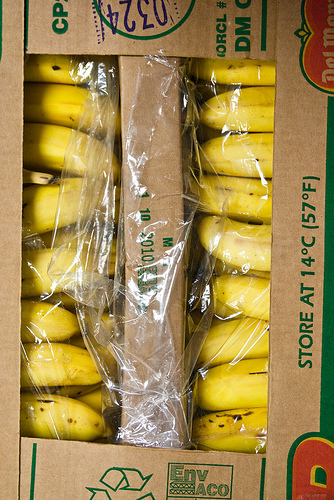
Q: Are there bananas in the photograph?
A: Yes, there are bananas.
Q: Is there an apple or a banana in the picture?
A: Yes, there are bananas.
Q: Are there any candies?
A: No, there are no candies.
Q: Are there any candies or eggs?
A: No, there are no candies or eggs.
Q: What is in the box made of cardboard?
A: The bananas are in the box.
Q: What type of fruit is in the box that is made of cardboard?
A: The fruits are bananas.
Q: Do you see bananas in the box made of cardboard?
A: Yes, there are bananas in the box.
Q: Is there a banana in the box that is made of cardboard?
A: Yes, there are bananas in the box.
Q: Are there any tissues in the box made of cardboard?
A: No, there are bananas in the box.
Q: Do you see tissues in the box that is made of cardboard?
A: No, there are bananas in the box.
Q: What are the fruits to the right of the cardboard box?
A: The fruits are bananas.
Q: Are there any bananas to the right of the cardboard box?
A: Yes, there are bananas to the right of the box.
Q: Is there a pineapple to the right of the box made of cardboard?
A: No, there are bananas to the right of the box.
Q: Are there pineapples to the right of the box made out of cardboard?
A: No, there are bananas to the right of the box.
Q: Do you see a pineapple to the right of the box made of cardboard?
A: No, there are bananas to the right of the box.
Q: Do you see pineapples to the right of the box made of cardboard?
A: No, there are bananas to the right of the box.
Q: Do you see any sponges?
A: No, there are no sponges.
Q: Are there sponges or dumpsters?
A: No, there are no sponges or dumpsters.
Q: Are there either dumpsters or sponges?
A: No, there are no sponges or dumpsters.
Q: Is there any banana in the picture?
A: Yes, there are bananas.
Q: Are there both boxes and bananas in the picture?
A: Yes, there are both bananas and a box.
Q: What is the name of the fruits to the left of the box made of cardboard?
A: The fruits are bananas.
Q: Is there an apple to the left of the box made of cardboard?
A: No, there are bananas to the left of the box.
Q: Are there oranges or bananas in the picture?
A: Yes, there are bananas.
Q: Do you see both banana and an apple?
A: No, there are bananas but no apples.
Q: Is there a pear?
A: No, there are no pears.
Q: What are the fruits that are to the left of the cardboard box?
A: The fruits are bananas.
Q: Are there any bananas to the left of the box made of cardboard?
A: Yes, there are bananas to the left of the box.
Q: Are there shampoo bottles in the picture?
A: No, there are no shampoo bottles.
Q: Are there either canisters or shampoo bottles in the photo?
A: No, there are no shampoo bottles or canisters.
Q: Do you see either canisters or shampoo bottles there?
A: No, there are no shampoo bottles or canisters.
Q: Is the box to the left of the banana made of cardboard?
A: Yes, the box is made of cardboard.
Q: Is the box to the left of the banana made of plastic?
A: No, the box is made of cardboard.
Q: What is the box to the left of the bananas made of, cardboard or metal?
A: The box is made of cardboard.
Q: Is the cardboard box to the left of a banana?
A: Yes, the box is to the left of a banana.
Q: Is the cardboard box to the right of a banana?
A: No, the box is to the left of a banana.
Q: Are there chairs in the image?
A: No, there are no chairs.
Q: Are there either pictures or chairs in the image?
A: No, there are no chairs or pictures.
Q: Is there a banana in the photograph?
A: Yes, there are bananas.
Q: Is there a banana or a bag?
A: Yes, there are bananas.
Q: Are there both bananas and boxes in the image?
A: Yes, there are both bananas and a box.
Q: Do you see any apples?
A: No, there are no apples.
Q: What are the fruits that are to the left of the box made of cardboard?
A: The fruits are bananas.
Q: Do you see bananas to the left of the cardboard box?
A: Yes, there are bananas to the left of the box.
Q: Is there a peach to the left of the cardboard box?
A: No, there are bananas to the left of the box.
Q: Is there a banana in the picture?
A: Yes, there is a banana.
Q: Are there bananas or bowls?
A: Yes, there is a banana.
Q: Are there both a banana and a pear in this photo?
A: No, there is a banana but no pears.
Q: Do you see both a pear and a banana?
A: No, there is a banana but no pears.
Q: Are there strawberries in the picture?
A: No, there are no strawberries.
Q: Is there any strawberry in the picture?
A: No, there are no strawberries.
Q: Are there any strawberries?
A: No, there are no strawberries.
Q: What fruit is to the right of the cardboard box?
A: The fruit is a banana.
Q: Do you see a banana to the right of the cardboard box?
A: Yes, there is a banana to the right of the box.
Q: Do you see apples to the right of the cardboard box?
A: No, there is a banana to the right of the box.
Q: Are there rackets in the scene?
A: No, there are no rackets.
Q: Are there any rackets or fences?
A: No, there are no rackets or fences.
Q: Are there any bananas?
A: Yes, there is a banana.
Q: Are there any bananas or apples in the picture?
A: Yes, there is a banana.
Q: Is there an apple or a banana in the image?
A: Yes, there is a banana.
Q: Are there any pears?
A: No, there are no pears.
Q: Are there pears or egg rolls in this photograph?
A: No, there are no pears or egg rolls.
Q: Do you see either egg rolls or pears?
A: No, there are no pears or egg rolls.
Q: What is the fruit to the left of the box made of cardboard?
A: The fruit is a banana.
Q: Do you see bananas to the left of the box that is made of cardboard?
A: Yes, there is a banana to the left of the box.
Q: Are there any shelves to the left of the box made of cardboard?
A: No, there is a banana to the left of the box.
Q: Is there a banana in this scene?
A: Yes, there is a banana.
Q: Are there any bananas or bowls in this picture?
A: Yes, there is a banana.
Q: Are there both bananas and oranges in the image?
A: No, there is a banana but no oranges.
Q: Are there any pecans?
A: No, there are no pecans.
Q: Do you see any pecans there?
A: No, there are no pecans.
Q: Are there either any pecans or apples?
A: No, there are no pecans or apples.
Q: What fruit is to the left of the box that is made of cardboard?
A: The fruit is a banana.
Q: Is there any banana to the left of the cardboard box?
A: Yes, there is a banana to the left of the box.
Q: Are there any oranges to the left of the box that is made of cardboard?
A: No, there is a banana to the left of the box.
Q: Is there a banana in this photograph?
A: Yes, there is a banana.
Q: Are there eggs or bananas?
A: Yes, there is a banana.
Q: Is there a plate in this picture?
A: No, there are no plates.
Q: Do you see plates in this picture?
A: No, there are no plates.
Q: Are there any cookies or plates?
A: No, there are no plates or cookies.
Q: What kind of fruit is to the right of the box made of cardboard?
A: The fruit is a banana.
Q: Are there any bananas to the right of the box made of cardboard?
A: Yes, there is a banana to the right of the box.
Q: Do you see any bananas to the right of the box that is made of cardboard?
A: Yes, there is a banana to the right of the box.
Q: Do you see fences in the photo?
A: No, there are no fences.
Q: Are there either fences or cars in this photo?
A: No, there are no fences or cars.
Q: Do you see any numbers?
A: Yes, there are numbers.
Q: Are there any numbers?
A: Yes, there are numbers.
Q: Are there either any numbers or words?
A: Yes, there are numbers.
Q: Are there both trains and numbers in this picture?
A: No, there are numbers but no trains.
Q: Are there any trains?
A: No, there are no trains.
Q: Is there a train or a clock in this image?
A: No, there are no trains or clocks.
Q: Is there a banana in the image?
A: Yes, there is a banana.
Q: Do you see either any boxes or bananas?
A: Yes, there is a banana.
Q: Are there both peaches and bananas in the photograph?
A: No, there is a banana but no peaches.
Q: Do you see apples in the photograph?
A: No, there are no apples.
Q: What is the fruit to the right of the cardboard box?
A: The fruit is a banana.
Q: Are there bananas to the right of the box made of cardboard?
A: Yes, there is a banana to the right of the box.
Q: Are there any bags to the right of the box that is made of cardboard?
A: No, there is a banana to the right of the box.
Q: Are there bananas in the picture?
A: Yes, there is a banana.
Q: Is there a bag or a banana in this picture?
A: Yes, there is a banana.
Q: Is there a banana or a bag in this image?
A: Yes, there is a banana.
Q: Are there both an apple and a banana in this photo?
A: No, there is a banana but no apples.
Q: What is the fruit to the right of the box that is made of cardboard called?
A: The fruit is a banana.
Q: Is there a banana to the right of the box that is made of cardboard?
A: Yes, there is a banana to the right of the box.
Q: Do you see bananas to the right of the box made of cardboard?
A: Yes, there is a banana to the right of the box.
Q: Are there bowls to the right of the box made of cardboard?
A: No, there is a banana to the right of the box.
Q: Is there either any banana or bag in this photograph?
A: Yes, there are bananas.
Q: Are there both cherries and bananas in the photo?
A: No, there are bananas but no cherries.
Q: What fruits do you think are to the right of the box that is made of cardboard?
A: The fruits are bananas.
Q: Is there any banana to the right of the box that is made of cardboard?
A: Yes, there are bananas to the right of the box.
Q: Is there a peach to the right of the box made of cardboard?
A: No, there are bananas to the right of the box.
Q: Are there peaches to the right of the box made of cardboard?
A: No, there are bananas to the right of the box.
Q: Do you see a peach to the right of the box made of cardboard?
A: No, there are bananas to the right of the box.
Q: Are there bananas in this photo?
A: Yes, there are bananas.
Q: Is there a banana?
A: Yes, there are bananas.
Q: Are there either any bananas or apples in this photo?
A: Yes, there are bananas.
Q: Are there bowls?
A: No, there are no bowls.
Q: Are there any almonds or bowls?
A: No, there are no bowls or almonds.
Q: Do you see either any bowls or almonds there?
A: No, there are no bowls or almonds.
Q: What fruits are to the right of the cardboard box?
A: The fruits are bananas.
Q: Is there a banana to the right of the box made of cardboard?
A: Yes, there are bananas to the right of the box.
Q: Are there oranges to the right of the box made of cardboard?
A: No, there are bananas to the right of the box.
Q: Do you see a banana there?
A: Yes, there are bananas.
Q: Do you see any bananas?
A: Yes, there are bananas.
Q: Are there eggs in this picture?
A: No, there are no eggs.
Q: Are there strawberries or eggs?
A: No, there are no eggs or strawberries.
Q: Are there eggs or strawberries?
A: No, there are no eggs or strawberries.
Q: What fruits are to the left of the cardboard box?
A: The fruits are bananas.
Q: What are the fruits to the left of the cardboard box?
A: The fruits are bananas.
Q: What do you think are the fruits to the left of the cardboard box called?
A: The fruits are bananas.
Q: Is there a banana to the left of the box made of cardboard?
A: Yes, there are bananas to the left of the box.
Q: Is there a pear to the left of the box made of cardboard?
A: No, there are bananas to the left of the box.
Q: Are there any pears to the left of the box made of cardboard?
A: No, there are bananas to the left of the box.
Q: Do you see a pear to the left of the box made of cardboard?
A: No, there are bananas to the left of the box.